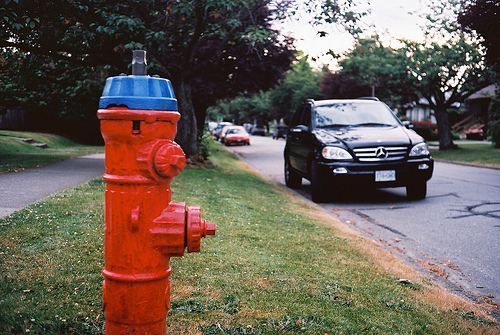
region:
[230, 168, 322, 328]
the grass is green and clear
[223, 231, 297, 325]
the grass is green and clear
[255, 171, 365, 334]
the grass is green and clear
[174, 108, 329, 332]
the grass is green and clear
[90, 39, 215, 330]
a red and blue fire hyrdrant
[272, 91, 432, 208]
a parked black vehicle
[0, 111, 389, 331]
a patch of green grass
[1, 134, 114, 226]
a grey paved sidewalk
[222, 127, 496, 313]
a paved city street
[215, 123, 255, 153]
a parked red car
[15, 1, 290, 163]
a large green tree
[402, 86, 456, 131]
a white house in distance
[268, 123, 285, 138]
a dark colored parked car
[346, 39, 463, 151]
a large green tree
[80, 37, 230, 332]
red and blue fire hydrant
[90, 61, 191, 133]
blue top to a fire hydrant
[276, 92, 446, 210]
black vehicle parked by curb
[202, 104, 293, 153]
cars parked on both sides of street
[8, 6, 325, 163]
large green trees along the road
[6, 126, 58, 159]
two cement steps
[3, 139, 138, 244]
a grey sidewalk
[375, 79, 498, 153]
houses along the street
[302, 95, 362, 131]
reflection of tree leafs in car window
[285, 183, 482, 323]
dried out brown grass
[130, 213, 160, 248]
red paint on hydrant.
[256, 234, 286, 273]
grass on the ground.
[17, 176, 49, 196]
concrete sidewalk by the grass.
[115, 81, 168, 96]
blue paint on hydrant.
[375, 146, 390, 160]
logo on front of car.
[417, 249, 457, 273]
leaves in the street.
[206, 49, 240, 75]
green leaves on the tree.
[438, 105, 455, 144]
trunk of the tree.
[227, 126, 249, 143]
red car parked by the curb.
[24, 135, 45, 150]
steps up the slope.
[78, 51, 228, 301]
The fire hydrant is orange and blue.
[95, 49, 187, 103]
Top of the hydrant is blue.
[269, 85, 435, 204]
The car is parked on the sidewalk.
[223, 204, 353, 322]
The grass is green and brown.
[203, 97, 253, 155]
Cars parked along the sidewalk.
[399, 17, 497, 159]
The tree is in front of the house.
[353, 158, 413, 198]
A license plate in front of the car.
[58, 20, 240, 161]
A big green tree on the grass.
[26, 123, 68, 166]
Stairs to the front of the house.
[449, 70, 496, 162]
A house on the other side of the street.